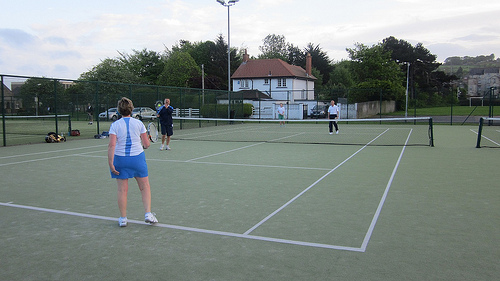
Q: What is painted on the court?
A: White lines.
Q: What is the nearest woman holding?
A: A tennis racket.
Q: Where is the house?
A: Behind the fence.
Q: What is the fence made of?
A: Chain link.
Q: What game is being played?
A: Tennis.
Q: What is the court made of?
A: Concrete.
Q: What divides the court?
A: Net.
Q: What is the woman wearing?
A: Skirt.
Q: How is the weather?
A: Overcast.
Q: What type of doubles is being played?
A: Mixed.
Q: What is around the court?
A: Fence.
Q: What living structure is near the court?
A: House.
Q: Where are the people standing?
A: Tennis court.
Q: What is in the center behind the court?
A: House.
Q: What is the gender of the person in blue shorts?
A: Female.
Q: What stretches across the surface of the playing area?
A: Net.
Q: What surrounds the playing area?
A: Fence.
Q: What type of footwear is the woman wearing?
A: Tennis shoes.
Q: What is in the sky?
A: Clouds.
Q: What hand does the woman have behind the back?
A: Left.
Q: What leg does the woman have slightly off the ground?
A: Right.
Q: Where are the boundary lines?
A: All over the tennis court.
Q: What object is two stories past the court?
A: 2 story house.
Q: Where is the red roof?
A: On a 2 story home.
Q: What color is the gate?
A: Black.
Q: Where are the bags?
A: By the gate.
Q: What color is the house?
A: White.